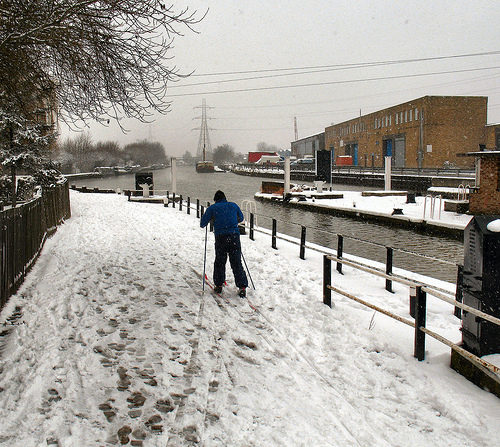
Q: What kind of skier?
A: Cross country.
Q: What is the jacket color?
A: Blue.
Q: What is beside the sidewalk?
A: Canal.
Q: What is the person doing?
A: Skiing.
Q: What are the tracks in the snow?
A: Footprints.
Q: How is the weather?
A: It is snowing.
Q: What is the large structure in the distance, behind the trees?
A: A transmission tower.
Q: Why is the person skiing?
A: To move through the snow faster.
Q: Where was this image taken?
A: On a riverbank.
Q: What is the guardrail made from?
A: Metal.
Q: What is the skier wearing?
A: Snow pants, a jacket, and a hat.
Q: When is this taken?
A: Daytime.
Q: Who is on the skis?
A: A skier.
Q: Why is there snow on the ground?
A: It is winter.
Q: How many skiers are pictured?
A: One.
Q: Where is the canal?
A: To the left of the skier.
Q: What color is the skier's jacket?
A: Blue.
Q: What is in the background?
A: Buildings.